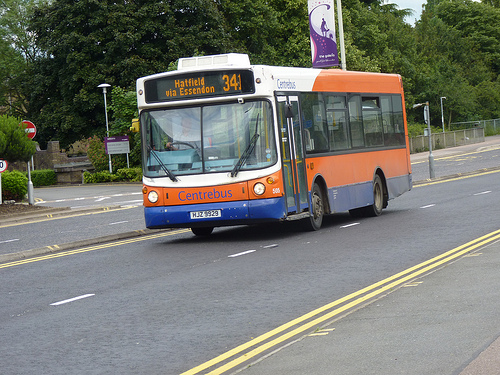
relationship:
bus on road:
[136, 52, 414, 237] [0, 134, 499, 373]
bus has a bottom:
[136, 52, 414, 237] [125, 164, 427, 247]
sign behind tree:
[18, 119, 38, 140] [0, 109, 37, 214]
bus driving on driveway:
[130, 51, 414, 229] [0, 145, 499, 373]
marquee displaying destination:
[153, 72, 244, 100] [162, 75, 216, 98]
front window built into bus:
[203, 98, 277, 173] [130, 51, 414, 229]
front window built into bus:
[138, 105, 203, 177] [130, 51, 414, 229]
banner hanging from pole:
[307, 0, 339, 68] [335, 0, 346, 68]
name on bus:
[177, 187, 232, 200] [130, 51, 414, 229]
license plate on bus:
[182, 206, 227, 224] [130, 51, 414, 229]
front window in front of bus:
[203, 98, 277, 173] [130, 51, 414, 229]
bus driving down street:
[130, 51, 414, 229] [5, 148, 494, 373]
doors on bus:
[276, 95, 299, 213] [136, 52, 414, 237]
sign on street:
[104, 135, 131, 154] [0, 130, 497, 370]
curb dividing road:
[184, 226, 486, 372] [2, 148, 493, 367]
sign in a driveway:
[18, 119, 38, 140] [6, 170, 136, 233]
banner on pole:
[307, 0, 339, 68] [335, 0, 347, 70]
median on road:
[49, 293, 96, 306] [28, 250, 489, 370]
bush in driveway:
[5, 171, 31, 206] [33, 181, 135, 203]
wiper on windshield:
[147, 144, 172, 179] [139, 107, 269, 168]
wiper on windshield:
[230, 130, 262, 173] [139, 107, 269, 168]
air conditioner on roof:
[175, 53, 245, 70] [136, 63, 386, 81]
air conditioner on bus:
[175, 53, 245, 70] [130, 51, 414, 229]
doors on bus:
[276, 95, 299, 213] [137, 63, 414, 233]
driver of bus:
[164, 119, 201, 151] [130, 51, 414, 229]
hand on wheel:
[165, 141, 172, 150] [157, 137, 191, 154]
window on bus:
[360, 93, 382, 142] [130, 51, 414, 229]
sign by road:
[18, 119, 38, 140] [28, 210, 137, 368]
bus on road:
[136, 52, 414, 237] [19, 176, 459, 323]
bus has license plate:
[136, 52, 414, 237] [184, 202, 222, 222]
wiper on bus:
[228, 112, 262, 178] [136, 52, 414, 237]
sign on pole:
[22, 118, 38, 148] [24, 138, 36, 207]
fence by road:
[413, 118, 487, 152] [0, 134, 499, 373]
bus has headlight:
[136, 52, 414, 237] [252, 178, 266, 199]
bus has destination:
[130, 51, 414, 229] [164, 77, 215, 98]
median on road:
[4, 231, 147, 269] [4, 216, 498, 365]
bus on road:
[136, 52, 414, 237] [15, 232, 498, 362]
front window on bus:
[203, 98, 277, 173] [130, 51, 414, 229]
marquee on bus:
[155, 73, 242, 100] [130, 51, 414, 229]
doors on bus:
[266, 87, 312, 218] [136, 52, 414, 237]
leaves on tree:
[412, 43, 438, 78] [389, 3, 496, 114]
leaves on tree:
[255, 24, 285, 60] [185, 2, 316, 67]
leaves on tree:
[363, 47, 373, 53] [415, 0, 493, 130]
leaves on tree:
[363, 47, 373, 53] [411, 6, 493, 139]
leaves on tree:
[363, 47, 373, 53] [423, 0, 498, 136]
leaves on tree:
[363, 47, 373, 53] [415, 11, 485, 131]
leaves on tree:
[42, 87, 71, 126] [25, 43, 94, 155]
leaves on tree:
[58, 62, 89, 102] [25, 55, 103, 161]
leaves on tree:
[52, 46, 116, 73] [41, 9, 131, 163]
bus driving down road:
[130, 51, 414, 229] [27, 226, 474, 366]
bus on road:
[130, 51, 414, 229] [15, 232, 498, 362]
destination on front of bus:
[139, 63, 259, 101] [116, 35, 416, 245]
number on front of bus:
[215, 68, 245, 100] [136, 52, 414, 237]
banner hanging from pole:
[307, 0, 339, 72] [332, 0, 353, 69]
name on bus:
[165, 182, 238, 202] [136, 52, 414, 237]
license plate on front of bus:
[189, 208, 223, 219] [130, 51, 414, 229]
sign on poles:
[104, 135, 130, 156] [101, 83, 120, 172]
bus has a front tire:
[130, 51, 414, 229] [307, 177, 330, 227]